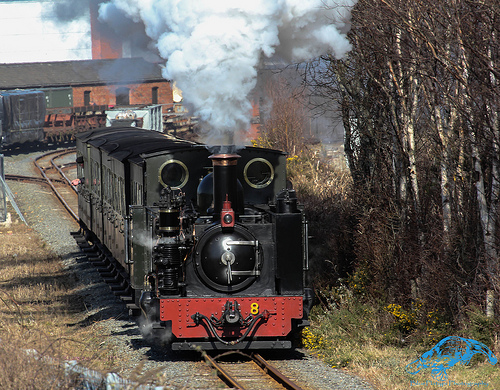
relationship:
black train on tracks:
[70, 126, 314, 348] [184, 342, 310, 388]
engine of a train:
[73, 124, 349, 356] [76, 97, 350, 382]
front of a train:
[143, 148, 313, 360] [76, 97, 350, 382]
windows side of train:
[77, 156, 124, 216] [73, 103, 310, 350]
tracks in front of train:
[208, 359, 291, 380] [50, 100, 332, 355]